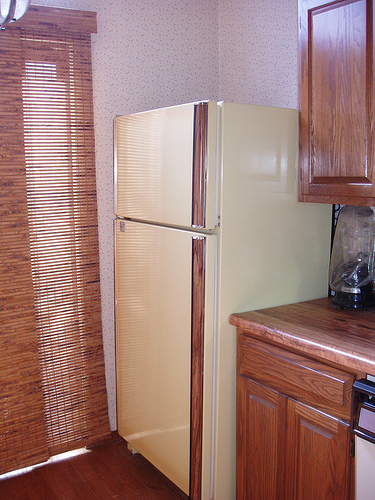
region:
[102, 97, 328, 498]
light yellow fridge with wood trim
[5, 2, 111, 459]
brown wooden blinds covering window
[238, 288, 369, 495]
brown cabinet beside fridge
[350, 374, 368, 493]
edge of black and white dishwasher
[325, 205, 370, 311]
black blending sitting on counter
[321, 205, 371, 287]
plastic bag over blender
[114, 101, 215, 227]
door for freezer compartment of fridge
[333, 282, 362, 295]
silver buttons on blender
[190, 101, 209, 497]
wooden trim on fridge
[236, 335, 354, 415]
drawer over two cabinet doors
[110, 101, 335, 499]
A cream colored refrigerator.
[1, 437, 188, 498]
Brown hardwood floors.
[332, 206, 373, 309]
A black blender.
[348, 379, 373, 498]
Part of a dishwasher.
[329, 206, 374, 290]
A plastic bag covering a blender.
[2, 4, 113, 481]
Brown long wooden blinds.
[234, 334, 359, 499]
Wooden cabinets under the countertop.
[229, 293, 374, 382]
A brown wooden countertop.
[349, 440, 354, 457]
A dark colored door hinge.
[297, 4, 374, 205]
A wooden cabinet over the countertop.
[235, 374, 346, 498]
two doors on brown cabinets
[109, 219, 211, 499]
door to fridge with brown trim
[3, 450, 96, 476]
sliver of light underneath blinds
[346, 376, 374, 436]
black top of dishwasher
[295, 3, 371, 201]
brown door to top cabinet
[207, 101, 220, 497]
white strip on fridge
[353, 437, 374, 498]
white part of dishwasher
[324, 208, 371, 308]
blender with plastic covering it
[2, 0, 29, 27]
light hanging from ceiling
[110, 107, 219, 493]
doors to yellow fridge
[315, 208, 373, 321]
A blender on a counter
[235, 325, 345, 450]
Two wooden cabnet doors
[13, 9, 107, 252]
Bland over a window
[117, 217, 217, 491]
A refrigerator door front.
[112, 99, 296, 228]
Top of a refrigerator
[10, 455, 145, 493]
A wooden plank floor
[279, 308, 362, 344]
A wooden counter top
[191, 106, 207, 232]
A handle on a refrigerator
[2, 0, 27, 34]
Light hanging from ceiling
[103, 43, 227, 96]
flowered wall paper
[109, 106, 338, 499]
white fridge and freezer combo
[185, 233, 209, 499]
strip of wood on the fridge door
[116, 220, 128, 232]
silver sticker on the door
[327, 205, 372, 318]
appliance sitting on the counter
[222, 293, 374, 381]
light brown wooden countertop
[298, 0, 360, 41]
light shining on the cabinet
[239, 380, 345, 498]
two wooden cabinet doors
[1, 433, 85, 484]
light shining under the curtain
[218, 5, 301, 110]
wallpaper on the wall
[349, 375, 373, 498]
white and black dishwasher